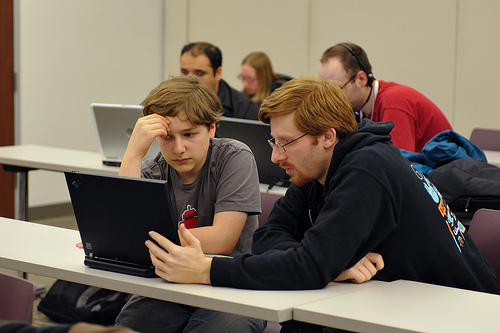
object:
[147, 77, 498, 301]
guy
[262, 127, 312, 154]
eyeglasses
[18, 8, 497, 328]
classroom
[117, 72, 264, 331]
person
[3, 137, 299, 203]
table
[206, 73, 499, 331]
people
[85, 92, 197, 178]
laptop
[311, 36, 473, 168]
guy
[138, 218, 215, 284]
hand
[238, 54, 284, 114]
girl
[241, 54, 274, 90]
long hair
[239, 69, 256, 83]
glasses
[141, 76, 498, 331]
man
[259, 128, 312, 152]
glasses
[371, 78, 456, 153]
sweater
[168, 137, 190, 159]
nose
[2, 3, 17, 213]
door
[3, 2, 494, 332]
room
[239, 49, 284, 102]
person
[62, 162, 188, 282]
computer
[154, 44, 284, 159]
person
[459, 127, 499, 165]
table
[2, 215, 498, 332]
tables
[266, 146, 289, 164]
nose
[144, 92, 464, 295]
person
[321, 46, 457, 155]
person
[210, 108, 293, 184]
computer